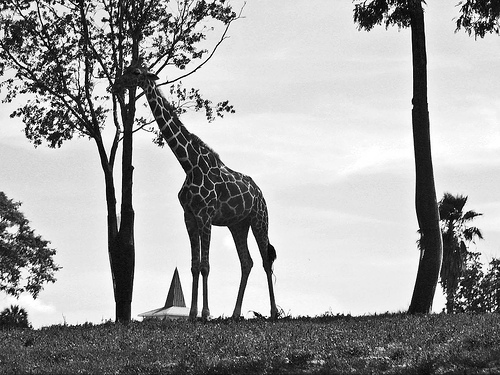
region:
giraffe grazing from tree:
[4, 1, 284, 325]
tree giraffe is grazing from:
[4, 7, 231, 321]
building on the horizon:
[130, 264, 200, 326]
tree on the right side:
[361, 5, 464, 309]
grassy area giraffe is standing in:
[10, 305, 487, 366]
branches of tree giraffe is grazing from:
[9, 10, 228, 237]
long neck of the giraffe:
[147, 90, 207, 167]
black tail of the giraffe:
[270, 243, 277, 269]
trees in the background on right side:
[425, 178, 497, 307]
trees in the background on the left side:
[3, 190, 62, 327]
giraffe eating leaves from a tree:
[106, 38, 294, 333]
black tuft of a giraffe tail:
[263, 230, 285, 281]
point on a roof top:
[161, 251, 188, 316]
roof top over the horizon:
[142, 253, 202, 335]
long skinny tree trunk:
[393, 15, 446, 349]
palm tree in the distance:
[418, 170, 491, 315]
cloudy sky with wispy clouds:
[273, 88, 380, 245]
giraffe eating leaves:
[108, 49, 160, 101]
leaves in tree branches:
[26, 13, 103, 123]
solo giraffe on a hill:
[102, 41, 322, 353]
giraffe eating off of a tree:
[110, 42, 287, 329]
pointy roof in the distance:
[145, 259, 200, 326]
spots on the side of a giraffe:
[198, 171, 242, 207]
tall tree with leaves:
[40, 14, 146, 324]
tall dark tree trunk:
[395, 3, 447, 320]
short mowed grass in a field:
[321, 328, 402, 365]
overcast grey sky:
[275, 81, 352, 213]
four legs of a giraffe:
[177, 227, 292, 320]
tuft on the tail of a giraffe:
[262, 236, 285, 281]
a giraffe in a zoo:
[98, 53, 443, 344]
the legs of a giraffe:
[177, 215, 288, 330]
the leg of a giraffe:
[255, 219, 283, 325]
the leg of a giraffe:
[226, 226, 255, 331]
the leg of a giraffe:
[200, 233, 217, 323]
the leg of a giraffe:
[191, 235, 201, 322]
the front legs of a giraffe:
[183, 218, 213, 323]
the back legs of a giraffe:
[228, 222, 290, 324]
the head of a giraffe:
[109, 65, 158, 101]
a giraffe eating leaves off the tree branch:
[110, 55, 280, 326]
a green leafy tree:
[0, 0, 245, 322]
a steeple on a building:
[138, 266, 189, 319]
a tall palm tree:
[353, 0, 442, 311]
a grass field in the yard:
[1, 313, 498, 373]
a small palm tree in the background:
[438, 193, 482, 313]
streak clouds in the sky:
[234, 38, 410, 149]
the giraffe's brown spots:
[190, 163, 205, 186]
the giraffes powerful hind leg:
[226, 218, 254, 318]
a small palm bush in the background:
[1, 305, 36, 333]